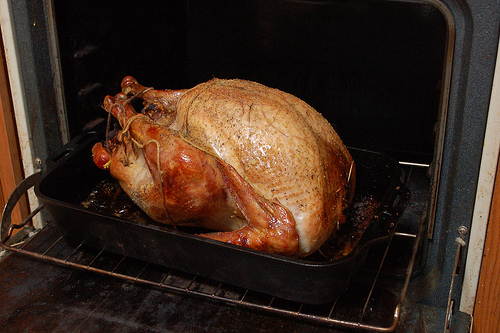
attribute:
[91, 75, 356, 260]
chicken — big 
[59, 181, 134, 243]
tray — metallic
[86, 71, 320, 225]
nicely browned — trussed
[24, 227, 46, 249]
grill — rusty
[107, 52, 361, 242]
chiken — big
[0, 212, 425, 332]
grill — metallic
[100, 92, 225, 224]
legs — trussed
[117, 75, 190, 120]
legs — trussed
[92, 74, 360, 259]
turkey — cooked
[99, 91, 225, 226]
drumstick — roasted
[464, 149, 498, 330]
wood — wooden, brown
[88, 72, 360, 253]
poultry — nicely browned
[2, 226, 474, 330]
oven door — open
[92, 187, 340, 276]
tray — black 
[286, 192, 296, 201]
dot — art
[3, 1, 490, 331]
oven door — opened